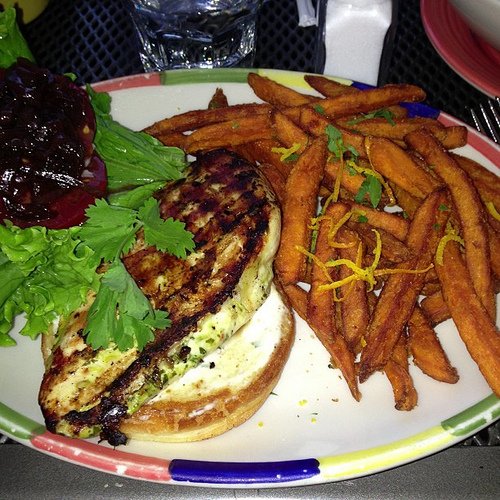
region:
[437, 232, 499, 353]
this is a fry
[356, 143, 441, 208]
this is a fry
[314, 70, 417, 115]
this is a fry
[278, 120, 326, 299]
this is a fry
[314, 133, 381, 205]
this is a fry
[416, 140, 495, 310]
this is a fry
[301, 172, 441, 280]
this is a fry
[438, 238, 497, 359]
fries on a plate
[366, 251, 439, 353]
fries on a plate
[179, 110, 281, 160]
fries on a plate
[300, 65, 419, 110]
fries on a plate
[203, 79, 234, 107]
fries on a plate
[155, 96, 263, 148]
fries on a plate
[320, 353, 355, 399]
fries on a plate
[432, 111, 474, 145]
fries on a plate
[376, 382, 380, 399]
edge of a plate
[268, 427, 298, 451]
side of a plate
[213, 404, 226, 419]
part of a bread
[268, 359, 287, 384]
part of a bread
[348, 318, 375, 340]
part of a chips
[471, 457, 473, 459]
part of a table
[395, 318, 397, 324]
part of a chip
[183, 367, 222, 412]
part of a bread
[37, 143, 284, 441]
grilled poached salmon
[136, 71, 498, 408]
golden brown sweet potato fries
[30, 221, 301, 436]
white grilled bread bun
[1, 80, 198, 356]
green arugula garnish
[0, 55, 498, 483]
white round plate edged with rainbow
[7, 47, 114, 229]
tomato and pickeled onion garnish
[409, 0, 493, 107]
small plate with pink edge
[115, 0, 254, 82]
clear empty drinking glass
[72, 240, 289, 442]
olive oile sprinkled on salmon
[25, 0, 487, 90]
blue rubber mat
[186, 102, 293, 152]
fries on a plate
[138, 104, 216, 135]
fries on a plate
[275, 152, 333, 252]
fries on a plate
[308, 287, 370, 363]
fries on a plate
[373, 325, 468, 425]
fries on a plate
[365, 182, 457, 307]
fries on a plate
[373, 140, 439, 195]
fries on a plate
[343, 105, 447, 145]
fries on a plate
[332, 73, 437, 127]
fries on a plate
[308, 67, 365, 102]
fries on a plate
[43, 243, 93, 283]
green lettuce on sandwich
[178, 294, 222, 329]
brown cooked meat on sandwich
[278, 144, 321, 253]
brown cooked french fries on white plate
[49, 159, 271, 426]
cooked chicken on bun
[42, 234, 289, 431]
round brown bun